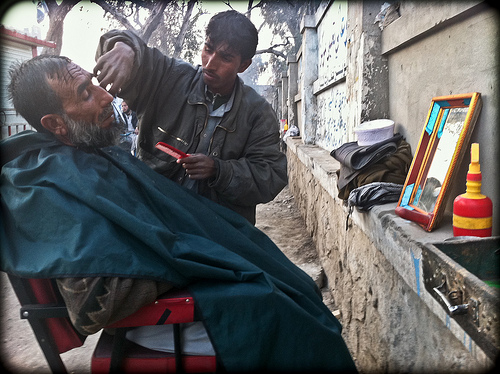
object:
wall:
[296, 39, 365, 103]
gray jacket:
[93, 30, 287, 228]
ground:
[272, 213, 314, 234]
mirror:
[393, 93, 483, 234]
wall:
[435, 1, 496, 60]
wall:
[364, 265, 431, 370]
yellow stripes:
[466, 183, 484, 199]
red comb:
[153, 142, 189, 160]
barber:
[92, 10, 288, 227]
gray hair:
[8, 55, 53, 112]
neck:
[61, 137, 71, 145]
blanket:
[0, 130, 359, 374]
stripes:
[452, 195, 493, 235]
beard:
[63, 114, 125, 152]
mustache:
[97, 105, 113, 122]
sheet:
[345, 182, 404, 231]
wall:
[414, 58, 448, 83]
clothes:
[328, 119, 412, 213]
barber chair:
[2, 279, 218, 374]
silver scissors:
[111, 102, 126, 125]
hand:
[176, 154, 215, 180]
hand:
[93, 42, 135, 96]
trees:
[25, 0, 184, 54]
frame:
[394, 91, 479, 232]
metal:
[32, 327, 68, 374]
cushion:
[25, 278, 82, 356]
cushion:
[95, 332, 218, 373]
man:
[0, 54, 217, 358]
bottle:
[452, 142, 492, 235]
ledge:
[282, 0, 499, 373]